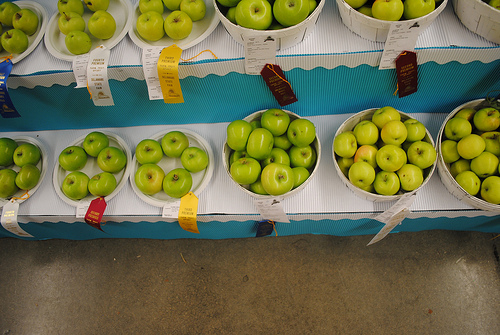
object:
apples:
[12, 143, 41, 168]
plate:
[0, 134, 49, 210]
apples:
[135, 138, 163, 165]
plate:
[128, 127, 215, 208]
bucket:
[331, 107, 439, 202]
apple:
[379, 119, 408, 146]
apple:
[406, 139, 437, 169]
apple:
[348, 161, 376, 187]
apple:
[234, 0, 271, 29]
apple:
[262, 146, 290, 165]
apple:
[444, 117, 473, 141]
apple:
[160, 131, 187, 158]